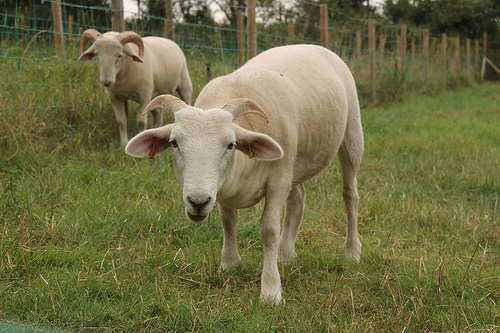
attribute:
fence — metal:
[351, 35, 446, 85]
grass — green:
[23, 210, 167, 324]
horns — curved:
[76, 29, 147, 61]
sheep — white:
[150, 22, 477, 326]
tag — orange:
[144, 133, 161, 160]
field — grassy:
[2, 45, 497, 332]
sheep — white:
[133, 40, 378, 302]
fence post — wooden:
[388, 20, 418, 105]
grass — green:
[1, 3, 499, 331]